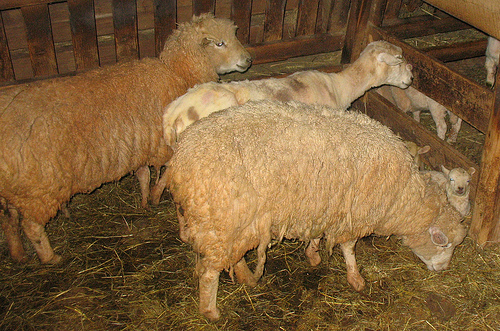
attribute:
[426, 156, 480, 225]
baby — small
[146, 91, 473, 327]
sheep — fluffy, white, standing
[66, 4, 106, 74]
pen — brown, wooden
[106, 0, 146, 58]
pen — wooden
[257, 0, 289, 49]
slat — wooden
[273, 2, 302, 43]
slat — wooden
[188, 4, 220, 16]
slat — wooden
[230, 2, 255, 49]
slat — wooden, brown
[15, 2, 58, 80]
slat — brown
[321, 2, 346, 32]
slat — wooden, brown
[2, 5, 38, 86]
slat — brown, wooden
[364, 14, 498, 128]
slat — brown, wooden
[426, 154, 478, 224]
sheep — baby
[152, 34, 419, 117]
sheep — shaved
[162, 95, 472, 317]
sheep — white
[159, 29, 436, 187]
sheep — standing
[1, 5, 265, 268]
sheep — standing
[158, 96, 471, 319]
wool — fluffy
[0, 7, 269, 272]
wool — dirty